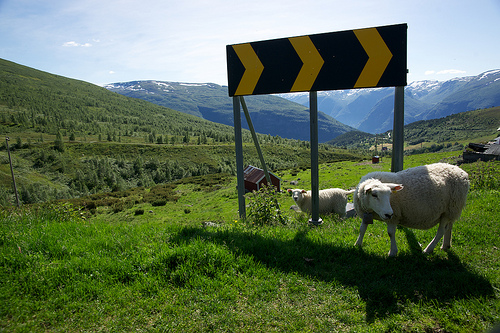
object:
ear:
[386, 183, 404, 191]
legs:
[349, 214, 371, 249]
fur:
[412, 180, 442, 215]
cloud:
[23, 34, 460, 84]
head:
[360, 179, 405, 221]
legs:
[422, 217, 449, 255]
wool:
[407, 171, 447, 211]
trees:
[75, 158, 175, 193]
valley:
[0, 127, 286, 212]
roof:
[242, 164, 282, 183]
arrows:
[349, 28, 393, 88]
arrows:
[288, 35, 322, 91]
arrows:
[229, 42, 264, 95]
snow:
[158, 82, 171, 87]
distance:
[0, 57, 500, 182]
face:
[371, 186, 394, 218]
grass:
[0, 218, 142, 317]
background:
[0, 0, 500, 163]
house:
[241, 161, 284, 196]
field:
[1, 56, 499, 330]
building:
[242, 164, 280, 193]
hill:
[99, 79, 377, 143]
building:
[463, 128, 500, 164]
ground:
[0, 133, 499, 330]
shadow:
[171, 222, 496, 322]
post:
[231, 95, 246, 223]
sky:
[1, 0, 499, 87]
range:
[118, 54, 452, 131]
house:
[369, 136, 393, 143]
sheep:
[284, 183, 356, 220]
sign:
[224, 21, 410, 98]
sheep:
[343, 147, 469, 257]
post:
[390, 88, 406, 236]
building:
[373, 137, 388, 142]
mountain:
[12, 60, 477, 173]